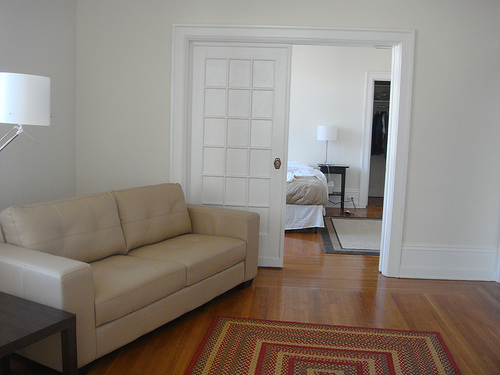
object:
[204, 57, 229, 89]
window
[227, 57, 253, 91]
window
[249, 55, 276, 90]
window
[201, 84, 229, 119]
window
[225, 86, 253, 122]
window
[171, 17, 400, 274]
bedroom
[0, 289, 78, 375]
end table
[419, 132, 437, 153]
ground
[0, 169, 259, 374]
beige couch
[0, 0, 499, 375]
living room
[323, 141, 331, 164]
silver base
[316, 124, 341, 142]
white shade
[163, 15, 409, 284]
entryway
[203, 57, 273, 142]
panes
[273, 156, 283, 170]
golden handle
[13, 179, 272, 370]
train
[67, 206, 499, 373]
floor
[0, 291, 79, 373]
table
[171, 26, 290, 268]
door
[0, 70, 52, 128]
lamp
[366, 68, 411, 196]
closet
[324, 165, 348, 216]
table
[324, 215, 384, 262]
rug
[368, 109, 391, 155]
clothes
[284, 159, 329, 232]
bed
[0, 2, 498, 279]
wall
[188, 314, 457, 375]
area rug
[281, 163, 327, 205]
comforter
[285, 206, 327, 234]
sheets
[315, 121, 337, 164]
lamp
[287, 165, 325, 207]
sheets